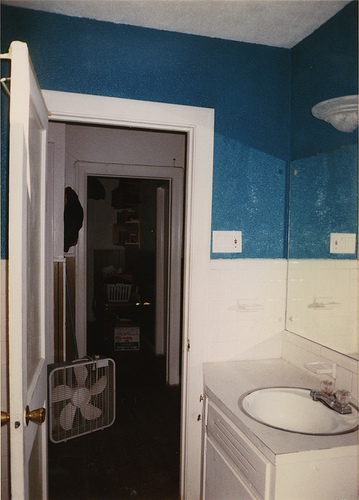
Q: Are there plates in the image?
A: Yes, there is a plate.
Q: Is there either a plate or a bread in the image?
A: Yes, there is a plate.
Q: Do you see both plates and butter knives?
A: No, there is a plate but no butter knives.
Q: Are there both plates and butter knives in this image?
A: No, there is a plate but no butter knives.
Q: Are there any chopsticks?
A: No, there are no chopsticks.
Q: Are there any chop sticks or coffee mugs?
A: No, there are no chop sticks or coffee mugs.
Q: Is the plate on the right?
A: Yes, the plate is on the right of the image.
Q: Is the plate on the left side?
A: No, the plate is on the right of the image.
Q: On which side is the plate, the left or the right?
A: The plate is on the right of the image.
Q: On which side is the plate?
A: The plate is on the right of the image.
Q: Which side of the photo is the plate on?
A: The plate is on the right of the image.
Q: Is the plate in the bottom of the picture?
A: Yes, the plate is in the bottom of the image.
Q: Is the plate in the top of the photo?
A: No, the plate is in the bottom of the image.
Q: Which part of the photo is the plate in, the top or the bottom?
A: The plate is in the bottom of the image.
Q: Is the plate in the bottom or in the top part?
A: The plate is in the bottom of the image.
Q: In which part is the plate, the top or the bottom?
A: The plate is in the bottom of the image.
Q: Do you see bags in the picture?
A: No, there are no bags.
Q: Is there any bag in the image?
A: No, there are no bags.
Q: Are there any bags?
A: No, there are no bags.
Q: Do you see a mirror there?
A: Yes, there is a mirror.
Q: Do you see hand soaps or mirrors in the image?
A: Yes, there is a mirror.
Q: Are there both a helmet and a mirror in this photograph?
A: No, there is a mirror but no helmets.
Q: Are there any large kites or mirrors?
A: Yes, there is a large mirror.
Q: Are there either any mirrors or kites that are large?
A: Yes, the mirror is large.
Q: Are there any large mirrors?
A: Yes, there is a large mirror.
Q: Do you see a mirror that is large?
A: Yes, there is a mirror that is large.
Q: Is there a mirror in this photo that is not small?
A: Yes, there is a large mirror.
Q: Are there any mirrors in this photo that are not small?
A: Yes, there is a large mirror.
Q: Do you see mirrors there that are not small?
A: Yes, there is a large mirror.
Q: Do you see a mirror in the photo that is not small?
A: Yes, there is a large mirror.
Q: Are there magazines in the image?
A: No, there are no magazines.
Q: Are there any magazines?
A: No, there are no magazines.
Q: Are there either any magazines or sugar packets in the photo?
A: No, there are no magazines or sugar packets.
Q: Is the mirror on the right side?
A: Yes, the mirror is on the right of the image.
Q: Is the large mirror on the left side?
A: No, the mirror is on the right of the image.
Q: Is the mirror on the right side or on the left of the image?
A: The mirror is on the right of the image.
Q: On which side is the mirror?
A: The mirror is on the right of the image.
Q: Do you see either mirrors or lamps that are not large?
A: No, there is a mirror but it is large.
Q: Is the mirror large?
A: Yes, the mirror is large.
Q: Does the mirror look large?
A: Yes, the mirror is large.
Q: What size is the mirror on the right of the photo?
A: The mirror is large.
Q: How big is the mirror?
A: The mirror is large.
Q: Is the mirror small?
A: No, the mirror is large.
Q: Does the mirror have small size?
A: No, the mirror is large.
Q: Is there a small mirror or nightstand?
A: No, there is a mirror but it is large.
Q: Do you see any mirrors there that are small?
A: No, there is a mirror but it is large.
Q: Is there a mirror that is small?
A: No, there is a mirror but it is large.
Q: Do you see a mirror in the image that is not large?
A: No, there is a mirror but it is large.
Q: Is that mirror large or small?
A: The mirror is large.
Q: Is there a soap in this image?
A: Yes, there is a soap.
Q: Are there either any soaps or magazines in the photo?
A: Yes, there is a soap.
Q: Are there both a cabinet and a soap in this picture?
A: Yes, there are both a soap and a cabinet.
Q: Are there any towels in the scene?
A: No, there are no towels.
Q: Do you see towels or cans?
A: No, there are no towels or cans.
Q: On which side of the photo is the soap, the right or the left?
A: The soap is on the right of the image.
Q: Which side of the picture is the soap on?
A: The soap is on the right of the image.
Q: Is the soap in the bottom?
A: Yes, the soap is in the bottom of the image.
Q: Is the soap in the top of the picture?
A: No, the soap is in the bottom of the image.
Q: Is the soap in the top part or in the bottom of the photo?
A: The soap is in the bottom of the image.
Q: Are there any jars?
A: No, there are no jars.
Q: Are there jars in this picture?
A: No, there are no jars.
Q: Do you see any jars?
A: No, there are no jars.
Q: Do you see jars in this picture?
A: No, there are no jars.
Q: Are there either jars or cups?
A: No, there are no jars or cups.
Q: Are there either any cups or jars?
A: No, there are no jars or cups.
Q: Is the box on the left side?
A: Yes, the box is on the left of the image.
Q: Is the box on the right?
A: No, the box is on the left of the image.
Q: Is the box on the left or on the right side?
A: The box is on the left of the image.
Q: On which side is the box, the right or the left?
A: The box is on the left of the image.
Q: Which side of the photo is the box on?
A: The box is on the left of the image.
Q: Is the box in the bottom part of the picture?
A: Yes, the box is in the bottom of the image.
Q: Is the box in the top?
A: No, the box is in the bottom of the image.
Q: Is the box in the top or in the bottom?
A: The box is in the bottom of the image.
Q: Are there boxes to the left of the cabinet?
A: Yes, there is a box to the left of the cabinet.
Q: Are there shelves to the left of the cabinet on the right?
A: No, there is a box to the left of the cabinet.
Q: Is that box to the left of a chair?
A: No, the box is to the left of the cabinet.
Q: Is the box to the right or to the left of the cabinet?
A: The box is to the left of the cabinet.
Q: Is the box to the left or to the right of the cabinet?
A: The box is to the left of the cabinet.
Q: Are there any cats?
A: No, there are no cats.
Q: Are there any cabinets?
A: Yes, there is a cabinet.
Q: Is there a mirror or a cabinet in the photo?
A: Yes, there is a cabinet.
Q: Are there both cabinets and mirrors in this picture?
A: Yes, there are both a cabinet and a mirror.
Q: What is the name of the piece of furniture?
A: The piece of furniture is a cabinet.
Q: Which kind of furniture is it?
A: The piece of furniture is a cabinet.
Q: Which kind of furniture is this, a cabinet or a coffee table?
A: That is a cabinet.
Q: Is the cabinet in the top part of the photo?
A: No, the cabinet is in the bottom of the image.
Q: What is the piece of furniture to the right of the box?
A: The piece of furniture is a cabinet.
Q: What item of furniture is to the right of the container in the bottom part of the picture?
A: The piece of furniture is a cabinet.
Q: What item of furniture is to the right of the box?
A: The piece of furniture is a cabinet.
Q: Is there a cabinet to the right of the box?
A: Yes, there is a cabinet to the right of the box.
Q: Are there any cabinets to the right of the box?
A: Yes, there is a cabinet to the right of the box.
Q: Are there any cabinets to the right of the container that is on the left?
A: Yes, there is a cabinet to the right of the box.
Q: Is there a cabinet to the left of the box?
A: No, the cabinet is to the right of the box.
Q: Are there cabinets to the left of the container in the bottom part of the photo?
A: No, the cabinet is to the right of the box.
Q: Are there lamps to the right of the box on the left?
A: No, there is a cabinet to the right of the box.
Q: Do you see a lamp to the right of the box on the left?
A: No, there is a cabinet to the right of the box.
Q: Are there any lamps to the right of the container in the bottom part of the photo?
A: No, there is a cabinet to the right of the box.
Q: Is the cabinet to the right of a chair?
A: No, the cabinet is to the right of the box.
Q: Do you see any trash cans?
A: No, there are no trash cans.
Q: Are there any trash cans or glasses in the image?
A: No, there are no trash cans or glasses.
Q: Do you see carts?
A: No, there are no carts.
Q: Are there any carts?
A: No, there are no carts.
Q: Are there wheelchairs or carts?
A: No, there are no carts or wheelchairs.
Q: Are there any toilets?
A: No, there are no toilets.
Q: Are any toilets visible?
A: No, there are no toilets.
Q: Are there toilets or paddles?
A: No, there are no toilets or paddles.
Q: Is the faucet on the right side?
A: Yes, the faucet is on the right of the image.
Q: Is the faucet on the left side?
A: No, the faucet is on the right of the image.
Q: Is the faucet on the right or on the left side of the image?
A: The faucet is on the right of the image.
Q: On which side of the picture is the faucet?
A: The faucet is on the right of the image.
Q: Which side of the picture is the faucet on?
A: The faucet is on the right of the image.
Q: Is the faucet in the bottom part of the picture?
A: Yes, the faucet is in the bottom of the image.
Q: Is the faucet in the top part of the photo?
A: No, the faucet is in the bottom of the image.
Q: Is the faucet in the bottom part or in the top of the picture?
A: The faucet is in the bottom of the image.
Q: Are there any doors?
A: Yes, there is a door.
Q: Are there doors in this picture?
A: Yes, there is a door.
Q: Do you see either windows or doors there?
A: Yes, there is a door.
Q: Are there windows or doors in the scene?
A: Yes, there is a door.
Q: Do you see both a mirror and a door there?
A: Yes, there are both a door and a mirror.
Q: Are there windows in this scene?
A: No, there are no windows.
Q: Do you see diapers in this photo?
A: No, there are no diapers.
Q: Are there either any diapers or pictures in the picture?
A: No, there are no diapers or pictures.